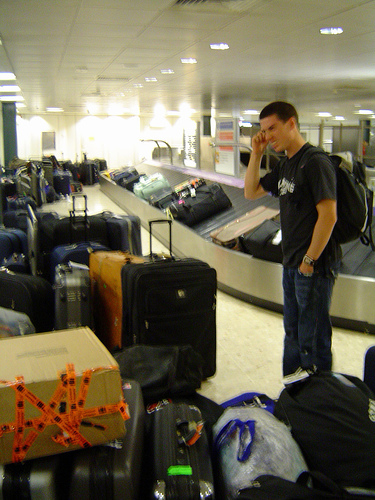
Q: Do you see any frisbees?
A: No, there are no frisbees.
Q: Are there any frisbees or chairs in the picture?
A: No, there are no frisbees or chairs.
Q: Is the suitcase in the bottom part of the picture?
A: Yes, the suitcase is in the bottom of the image.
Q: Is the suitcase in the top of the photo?
A: No, the suitcase is in the bottom of the image.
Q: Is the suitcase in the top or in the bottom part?
A: The suitcase is in the bottom of the image.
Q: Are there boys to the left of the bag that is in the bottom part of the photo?
A: No, there is a suitcase to the left of the bag.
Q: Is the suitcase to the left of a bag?
A: Yes, the suitcase is to the left of a bag.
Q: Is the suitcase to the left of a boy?
A: No, the suitcase is to the left of a bag.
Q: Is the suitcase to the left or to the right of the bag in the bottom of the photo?
A: The suitcase is to the left of the bag.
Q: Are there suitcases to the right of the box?
A: Yes, there is a suitcase to the right of the box.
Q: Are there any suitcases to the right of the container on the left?
A: Yes, there is a suitcase to the right of the box.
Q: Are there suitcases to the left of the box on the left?
A: No, the suitcase is to the right of the box.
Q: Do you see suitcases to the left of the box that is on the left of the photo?
A: No, the suitcase is to the right of the box.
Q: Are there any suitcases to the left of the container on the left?
A: No, the suitcase is to the right of the box.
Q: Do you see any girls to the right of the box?
A: No, there is a suitcase to the right of the box.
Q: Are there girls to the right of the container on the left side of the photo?
A: No, there is a suitcase to the right of the box.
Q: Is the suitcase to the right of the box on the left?
A: Yes, the suitcase is to the right of the box.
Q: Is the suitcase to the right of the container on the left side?
A: Yes, the suitcase is to the right of the box.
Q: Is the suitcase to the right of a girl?
A: No, the suitcase is to the right of the box.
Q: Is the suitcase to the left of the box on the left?
A: No, the suitcase is to the right of the box.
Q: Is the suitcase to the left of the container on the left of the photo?
A: No, the suitcase is to the right of the box.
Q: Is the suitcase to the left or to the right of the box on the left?
A: The suitcase is to the right of the box.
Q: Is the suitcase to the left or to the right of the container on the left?
A: The suitcase is to the right of the box.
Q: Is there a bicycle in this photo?
A: No, there are no bicycles.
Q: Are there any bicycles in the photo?
A: No, there are no bicycles.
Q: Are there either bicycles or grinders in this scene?
A: No, there are no bicycles or grinders.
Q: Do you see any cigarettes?
A: No, there are no cigarettes.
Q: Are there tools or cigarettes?
A: No, there are no cigarettes or tools.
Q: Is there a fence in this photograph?
A: No, there are no fences.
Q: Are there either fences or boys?
A: No, there are no fences or boys.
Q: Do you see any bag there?
A: Yes, there is a bag.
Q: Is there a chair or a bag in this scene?
A: Yes, there is a bag.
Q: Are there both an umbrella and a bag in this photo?
A: No, there is a bag but no umbrellas.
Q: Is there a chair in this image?
A: No, there are no chairs.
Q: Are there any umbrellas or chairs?
A: No, there are no chairs or umbrellas.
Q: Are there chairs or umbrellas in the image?
A: No, there are no chairs or umbrellas.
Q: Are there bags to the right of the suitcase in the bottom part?
A: Yes, there is a bag to the right of the suitcase.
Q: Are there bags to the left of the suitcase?
A: No, the bag is to the right of the suitcase.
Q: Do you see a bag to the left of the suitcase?
A: No, the bag is to the right of the suitcase.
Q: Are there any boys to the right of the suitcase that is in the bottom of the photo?
A: No, there is a bag to the right of the suitcase.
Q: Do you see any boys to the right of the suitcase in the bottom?
A: No, there is a bag to the right of the suitcase.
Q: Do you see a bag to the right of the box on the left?
A: Yes, there is a bag to the right of the box.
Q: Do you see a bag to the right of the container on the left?
A: Yes, there is a bag to the right of the box.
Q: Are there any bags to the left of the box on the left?
A: No, the bag is to the right of the box.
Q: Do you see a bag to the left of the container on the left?
A: No, the bag is to the right of the box.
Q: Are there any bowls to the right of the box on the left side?
A: No, there is a bag to the right of the box.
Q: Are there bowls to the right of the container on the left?
A: No, there is a bag to the right of the box.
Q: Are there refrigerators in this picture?
A: No, there are no refrigerators.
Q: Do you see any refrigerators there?
A: No, there are no refrigerators.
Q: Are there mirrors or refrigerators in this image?
A: No, there are no refrigerators or mirrors.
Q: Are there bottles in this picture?
A: No, there are no bottles.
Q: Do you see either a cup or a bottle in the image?
A: No, there are no bottles or cups.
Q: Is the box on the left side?
A: Yes, the box is on the left of the image.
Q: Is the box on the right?
A: No, the box is on the left of the image.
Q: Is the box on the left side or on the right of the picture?
A: The box is on the left of the image.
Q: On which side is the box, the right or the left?
A: The box is on the left of the image.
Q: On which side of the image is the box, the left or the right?
A: The box is on the left of the image.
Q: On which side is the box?
A: The box is on the left of the image.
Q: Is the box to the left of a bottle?
A: No, the box is to the left of the bag.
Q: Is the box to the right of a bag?
A: No, the box is to the left of a bag.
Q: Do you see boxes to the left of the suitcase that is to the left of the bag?
A: Yes, there is a box to the left of the suitcase.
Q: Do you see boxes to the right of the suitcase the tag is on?
A: No, the box is to the left of the suitcase.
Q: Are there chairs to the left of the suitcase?
A: No, there is a box to the left of the suitcase.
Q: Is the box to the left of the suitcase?
A: Yes, the box is to the left of the suitcase.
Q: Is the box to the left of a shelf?
A: No, the box is to the left of the suitcase.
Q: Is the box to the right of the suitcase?
A: No, the box is to the left of the suitcase.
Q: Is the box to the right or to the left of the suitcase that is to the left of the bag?
A: The box is to the left of the suitcase.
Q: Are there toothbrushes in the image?
A: No, there are no toothbrushes.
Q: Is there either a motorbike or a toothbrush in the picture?
A: No, there are no toothbrushes or motorcycles.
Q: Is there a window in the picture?
A: Yes, there are windows.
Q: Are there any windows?
A: Yes, there are windows.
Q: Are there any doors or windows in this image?
A: Yes, there are windows.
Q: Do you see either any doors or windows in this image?
A: Yes, there are windows.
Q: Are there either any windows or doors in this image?
A: Yes, there are windows.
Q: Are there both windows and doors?
A: No, there are windows but no doors.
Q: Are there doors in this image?
A: No, there are no doors.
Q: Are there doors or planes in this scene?
A: No, there are no doors or planes.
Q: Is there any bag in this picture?
A: Yes, there is a bag.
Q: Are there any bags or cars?
A: Yes, there is a bag.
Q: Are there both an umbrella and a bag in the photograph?
A: No, there is a bag but no umbrellas.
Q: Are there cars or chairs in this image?
A: No, there are no cars or chairs.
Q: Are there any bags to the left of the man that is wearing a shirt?
A: Yes, there is a bag to the left of the man.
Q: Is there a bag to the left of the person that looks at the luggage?
A: Yes, there is a bag to the left of the man.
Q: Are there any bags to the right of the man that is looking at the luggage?
A: No, the bag is to the left of the man.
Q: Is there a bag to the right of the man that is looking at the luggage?
A: No, the bag is to the left of the man.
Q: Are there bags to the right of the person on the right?
A: No, the bag is to the left of the man.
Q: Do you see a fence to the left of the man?
A: No, there is a bag to the left of the man.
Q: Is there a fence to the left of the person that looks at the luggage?
A: No, there is a bag to the left of the man.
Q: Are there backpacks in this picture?
A: Yes, there is a backpack.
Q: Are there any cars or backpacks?
A: Yes, there is a backpack.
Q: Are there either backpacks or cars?
A: Yes, there is a backpack.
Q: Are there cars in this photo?
A: No, there are no cars.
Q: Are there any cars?
A: No, there are no cars.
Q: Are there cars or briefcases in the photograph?
A: No, there are no cars or briefcases.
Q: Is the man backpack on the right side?
A: Yes, the backpack is on the right of the image.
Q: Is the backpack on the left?
A: No, the backpack is on the right of the image.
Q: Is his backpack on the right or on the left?
A: The backpack is on the right of the image.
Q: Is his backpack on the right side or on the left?
A: The backpack is on the right of the image.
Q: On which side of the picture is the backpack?
A: The backpack is on the right of the image.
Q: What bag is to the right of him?
A: The bag is a backpack.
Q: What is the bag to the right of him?
A: The bag is a backpack.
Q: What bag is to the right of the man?
A: The bag is a backpack.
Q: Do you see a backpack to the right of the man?
A: Yes, there is a backpack to the right of the man.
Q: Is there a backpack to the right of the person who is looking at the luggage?
A: Yes, there is a backpack to the right of the man.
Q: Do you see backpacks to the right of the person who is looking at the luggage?
A: Yes, there is a backpack to the right of the man.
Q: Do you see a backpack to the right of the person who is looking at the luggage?
A: Yes, there is a backpack to the right of the man.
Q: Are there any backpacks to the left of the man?
A: No, the backpack is to the right of the man.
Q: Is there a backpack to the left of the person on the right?
A: No, the backpack is to the right of the man.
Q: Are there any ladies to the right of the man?
A: No, there is a backpack to the right of the man.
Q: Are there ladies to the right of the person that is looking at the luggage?
A: No, there is a backpack to the right of the man.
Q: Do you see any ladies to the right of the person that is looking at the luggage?
A: No, there is a backpack to the right of the man.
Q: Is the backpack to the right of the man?
A: Yes, the backpack is to the right of the man.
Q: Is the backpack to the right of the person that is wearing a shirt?
A: Yes, the backpack is to the right of the man.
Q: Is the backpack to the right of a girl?
A: No, the backpack is to the right of the man.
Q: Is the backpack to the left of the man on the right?
A: No, the backpack is to the right of the man.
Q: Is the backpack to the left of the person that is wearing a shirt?
A: No, the backpack is to the right of the man.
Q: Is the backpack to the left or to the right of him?
A: The backpack is to the right of the man.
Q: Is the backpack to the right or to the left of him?
A: The backpack is to the right of the man.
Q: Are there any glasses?
A: No, there are no glasses.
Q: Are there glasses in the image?
A: No, there are no glasses.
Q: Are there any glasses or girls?
A: No, there are no glasses or girls.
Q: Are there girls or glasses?
A: No, there are no glasses or girls.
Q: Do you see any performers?
A: No, there are no performers.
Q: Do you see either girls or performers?
A: No, there are no performers or girls.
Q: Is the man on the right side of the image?
A: Yes, the man is on the right of the image.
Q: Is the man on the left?
A: No, the man is on the right of the image.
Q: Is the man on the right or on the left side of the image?
A: The man is on the right of the image.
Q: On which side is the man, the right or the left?
A: The man is on the right of the image.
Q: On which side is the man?
A: The man is on the right of the image.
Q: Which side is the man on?
A: The man is on the right of the image.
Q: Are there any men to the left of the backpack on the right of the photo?
A: Yes, there is a man to the left of the backpack.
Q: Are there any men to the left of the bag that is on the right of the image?
A: Yes, there is a man to the left of the backpack.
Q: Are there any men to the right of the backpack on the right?
A: No, the man is to the left of the backpack.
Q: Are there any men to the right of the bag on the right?
A: No, the man is to the left of the backpack.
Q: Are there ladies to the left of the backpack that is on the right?
A: No, there is a man to the left of the backpack.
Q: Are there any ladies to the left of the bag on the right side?
A: No, there is a man to the left of the backpack.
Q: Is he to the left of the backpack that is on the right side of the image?
A: Yes, the man is to the left of the backpack.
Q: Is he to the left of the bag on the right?
A: Yes, the man is to the left of the backpack.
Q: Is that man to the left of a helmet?
A: No, the man is to the left of the backpack.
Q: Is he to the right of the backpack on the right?
A: No, the man is to the left of the backpack.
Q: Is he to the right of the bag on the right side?
A: No, the man is to the left of the backpack.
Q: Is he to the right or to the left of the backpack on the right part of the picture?
A: The man is to the left of the backpack.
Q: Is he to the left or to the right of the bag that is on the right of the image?
A: The man is to the left of the backpack.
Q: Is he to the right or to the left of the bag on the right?
A: The man is to the left of the backpack.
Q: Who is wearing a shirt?
A: The man is wearing a shirt.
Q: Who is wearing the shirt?
A: The man is wearing a shirt.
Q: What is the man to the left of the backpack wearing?
A: The man is wearing a shirt.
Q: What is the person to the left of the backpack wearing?
A: The man is wearing a shirt.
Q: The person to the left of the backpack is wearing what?
A: The man is wearing a shirt.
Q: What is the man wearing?
A: The man is wearing a shirt.